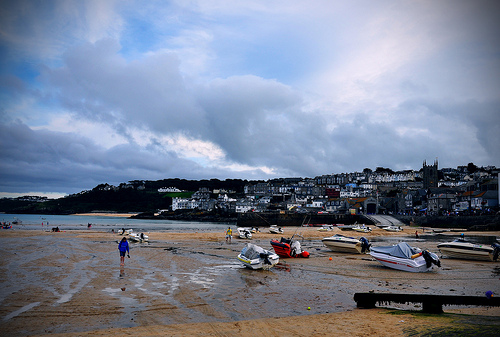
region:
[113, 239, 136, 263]
woman in blue jacket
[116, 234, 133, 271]
a woman standing on sand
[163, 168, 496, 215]
group of buildings on shore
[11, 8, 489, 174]
clouds in the sky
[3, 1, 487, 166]
clouds above the land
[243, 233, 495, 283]
5 boats on a shore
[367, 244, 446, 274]
one boat on a shore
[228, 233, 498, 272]
five boats on top of sand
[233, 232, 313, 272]
two boats on shore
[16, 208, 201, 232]
a body of water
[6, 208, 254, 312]
people in the beach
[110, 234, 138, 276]
woman walking in the beach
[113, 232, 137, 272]
woman wears blue top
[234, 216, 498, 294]
boats parking on the sand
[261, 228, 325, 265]
a red boat on the sand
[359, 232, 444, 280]
a white boat on the sand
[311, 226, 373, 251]
a white boat on the sand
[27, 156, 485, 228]
a city in front the ocean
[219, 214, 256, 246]
person near a boat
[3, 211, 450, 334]
sand is covered with water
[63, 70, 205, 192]
These are clouds in the sky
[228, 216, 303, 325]
This is a small boat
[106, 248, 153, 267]
This is a woman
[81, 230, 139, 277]
The woman is wearing a coat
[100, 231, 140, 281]
The coat is blue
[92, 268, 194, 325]
This is a sandy shore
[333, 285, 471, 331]
This is a small bench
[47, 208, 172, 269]
This is the ocean shore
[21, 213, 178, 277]
The water is light blue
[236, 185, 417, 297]
These are buildings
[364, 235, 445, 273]
white boat on sand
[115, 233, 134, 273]
person in blue shirt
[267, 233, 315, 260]
red boat in the sand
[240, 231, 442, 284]
boats in the sand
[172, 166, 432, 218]
buildings on a hillside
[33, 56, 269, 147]
clouds in a blue sky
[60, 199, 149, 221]
a small sandy beach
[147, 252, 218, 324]
water rivets on beach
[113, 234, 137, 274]
person toting small object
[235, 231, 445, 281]
four boats beached on shore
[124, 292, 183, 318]
Water on the sand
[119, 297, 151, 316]
Sand in the water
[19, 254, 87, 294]
Low tide on a beach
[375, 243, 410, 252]
A boat covered with a cloth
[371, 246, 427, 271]
A covered boat on the sand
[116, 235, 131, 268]
A person walking on wet sand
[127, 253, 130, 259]
A shoe in the hand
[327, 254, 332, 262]
A round object on the sand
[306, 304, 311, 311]
An object in the wet sand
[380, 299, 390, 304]
Loose debris hanging down